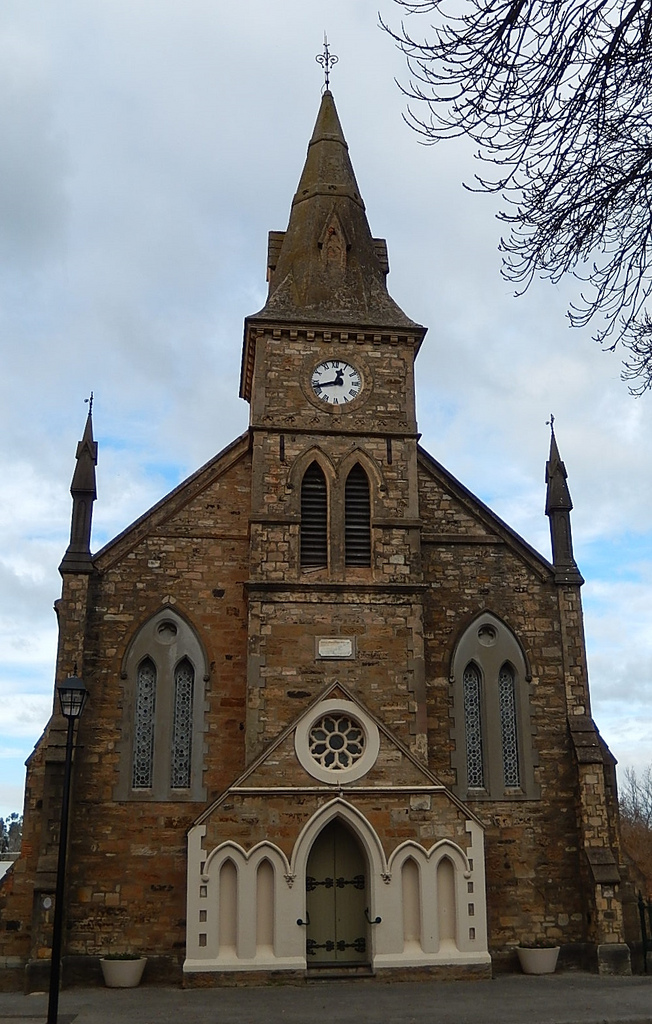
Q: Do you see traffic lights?
A: No, there are no traffic lights.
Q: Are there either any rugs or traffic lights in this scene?
A: No, there are no traffic lights or rugs.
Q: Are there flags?
A: No, there are no flags.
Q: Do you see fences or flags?
A: No, there are no flags or fences.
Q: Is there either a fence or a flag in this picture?
A: No, there are no flags or fences.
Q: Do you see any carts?
A: No, there are no carts.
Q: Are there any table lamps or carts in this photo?
A: No, there are no carts or table lamps.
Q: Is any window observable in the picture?
A: Yes, there is a window.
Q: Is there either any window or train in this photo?
A: Yes, there is a window.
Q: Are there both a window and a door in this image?
A: Yes, there are both a window and a door.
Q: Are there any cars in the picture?
A: No, there are no cars.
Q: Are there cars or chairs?
A: No, there are no cars or chairs.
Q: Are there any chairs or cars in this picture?
A: No, there are no cars or chairs.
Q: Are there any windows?
A: Yes, there is a window.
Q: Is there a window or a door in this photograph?
A: Yes, there is a window.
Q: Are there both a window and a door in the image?
A: Yes, there are both a window and a door.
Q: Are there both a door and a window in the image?
A: Yes, there are both a window and a door.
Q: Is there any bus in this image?
A: No, there are no buses.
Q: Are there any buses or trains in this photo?
A: No, there are no buses or trains.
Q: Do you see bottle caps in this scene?
A: No, there are no bottle caps.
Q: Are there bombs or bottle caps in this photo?
A: No, there are no bottle caps or bombs.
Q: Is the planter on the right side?
A: Yes, the planter is on the right of the image.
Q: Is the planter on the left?
A: No, the planter is on the right of the image.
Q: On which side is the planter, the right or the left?
A: The planter is on the right of the image.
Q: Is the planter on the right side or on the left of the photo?
A: The planter is on the right of the image.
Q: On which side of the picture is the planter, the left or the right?
A: The planter is on the right of the image.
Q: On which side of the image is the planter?
A: The planter is on the right of the image.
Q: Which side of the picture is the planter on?
A: The planter is on the right of the image.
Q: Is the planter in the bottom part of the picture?
A: Yes, the planter is in the bottom of the image.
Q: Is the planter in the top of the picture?
A: No, the planter is in the bottom of the image.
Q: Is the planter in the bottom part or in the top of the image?
A: The planter is in the bottom of the image.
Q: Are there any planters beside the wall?
A: Yes, there is a planter beside the wall.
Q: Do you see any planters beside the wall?
A: Yes, there is a planter beside the wall.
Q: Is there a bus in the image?
A: No, there are no buses.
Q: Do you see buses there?
A: No, there are no buses.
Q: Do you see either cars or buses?
A: No, there are no buses or cars.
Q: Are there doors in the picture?
A: Yes, there is a door.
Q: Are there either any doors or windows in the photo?
A: Yes, there is a door.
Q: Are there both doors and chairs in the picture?
A: No, there is a door but no chairs.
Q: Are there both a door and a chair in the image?
A: No, there is a door but no chairs.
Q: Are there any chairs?
A: No, there are no chairs.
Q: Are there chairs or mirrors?
A: No, there are no chairs or mirrors.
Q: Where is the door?
A: The door is at the building.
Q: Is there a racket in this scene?
A: No, there are no rackets.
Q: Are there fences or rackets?
A: No, there are no rackets or fences.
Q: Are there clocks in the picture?
A: Yes, there is a clock.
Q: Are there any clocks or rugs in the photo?
A: Yes, there is a clock.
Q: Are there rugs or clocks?
A: Yes, there is a clock.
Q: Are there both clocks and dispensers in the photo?
A: No, there is a clock but no dispensers.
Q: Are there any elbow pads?
A: No, there are no elbow pads.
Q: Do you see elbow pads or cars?
A: No, there are no elbow pads or cars.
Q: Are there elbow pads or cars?
A: No, there are no elbow pads or cars.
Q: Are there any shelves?
A: No, there are no shelves.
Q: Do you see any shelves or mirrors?
A: No, there are no shelves or mirrors.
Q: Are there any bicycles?
A: No, there are no bicycles.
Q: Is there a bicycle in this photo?
A: No, there are no bicycles.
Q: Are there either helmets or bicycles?
A: No, there are no bicycles or helmets.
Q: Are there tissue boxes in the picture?
A: No, there are no tissue boxes.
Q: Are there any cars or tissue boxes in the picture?
A: No, there are no tissue boxes or cars.